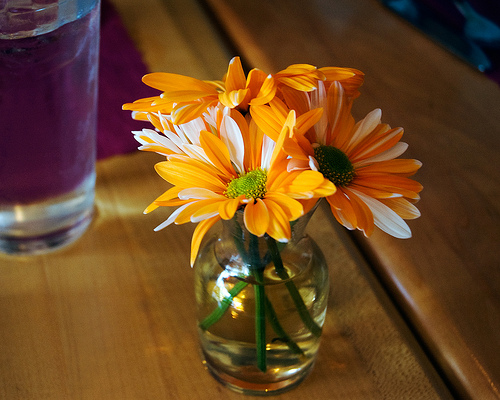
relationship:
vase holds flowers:
[190, 195, 330, 395] [130, 52, 420, 264]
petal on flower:
[219, 113, 246, 173] [150, 112, 333, 255]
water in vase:
[192, 231, 331, 384] [184, 186, 327, 396]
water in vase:
[192, 231, 331, 384] [176, 182, 332, 392]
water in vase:
[187, 245, 337, 386] [181, 215, 341, 382]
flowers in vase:
[140, 30, 417, 256] [181, 215, 341, 382]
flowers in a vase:
[122, 55, 422, 269] [189, 194, 366, 394]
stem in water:
[244, 232, 268, 370] [192, 236, 329, 393]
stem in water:
[231, 221, 304, 362] [192, 236, 329, 393]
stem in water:
[270, 239, 327, 336] [192, 236, 329, 393]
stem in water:
[190, 239, 296, 330] [192, 236, 329, 393]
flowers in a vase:
[122, 55, 422, 269] [190, 195, 330, 395]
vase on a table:
[190, 196, 330, 397] [86, 22, 476, 322]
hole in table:
[176, 5, 480, 397] [1, 2, 498, 397]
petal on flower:
[352, 191, 412, 240] [193, 69, 379, 189]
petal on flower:
[244, 197, 271, 238] [193, 69, 379, 189]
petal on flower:
[325, 80, 343, 147] [193, 69, 379, 189]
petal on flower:
[199, 127, 236, 179] [193, 69, 379, 189]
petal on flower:
[192, 216, 219, 266] [193, 69, 379, 189]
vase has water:
[190, 195, 330, 395] [192, 236, 329, 393]